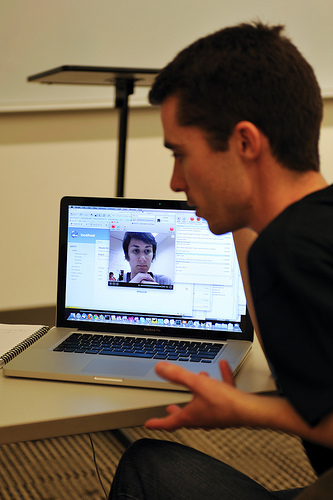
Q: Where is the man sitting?
A: In front of a computer.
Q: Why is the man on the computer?
A: On Skype talking to someone.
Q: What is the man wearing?
A: Blue jeans.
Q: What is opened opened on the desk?
A: A silver laptop.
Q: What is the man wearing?
A: A black shirt.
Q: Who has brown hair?
A: The man.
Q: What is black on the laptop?
A: The keys.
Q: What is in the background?
A: A black lamp.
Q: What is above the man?
A: A white ceiling.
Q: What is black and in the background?
A: A lamp.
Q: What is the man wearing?
A: A black shirt.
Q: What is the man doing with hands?
A: Gesturing.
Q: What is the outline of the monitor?
A: Black.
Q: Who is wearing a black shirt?
A: Young man.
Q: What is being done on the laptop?
A: Video chat.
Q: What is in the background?
A: Podium.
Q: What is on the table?
A: Laptop.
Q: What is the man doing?
A: Pointing.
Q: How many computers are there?
A: 1.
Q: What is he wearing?
A: Black top.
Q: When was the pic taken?
A: During the day.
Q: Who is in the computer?
A: A woman.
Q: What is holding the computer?
A: A desk.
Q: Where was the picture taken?
A: At a desk.